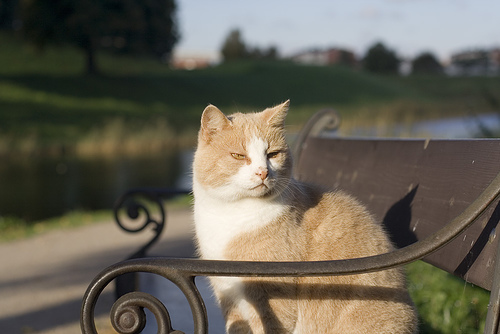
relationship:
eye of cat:
[266, 149, 283, 160] [164, 121, 441, 315]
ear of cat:
[201, 103, 233, 136] [186, 98, 420, 334]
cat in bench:
[186, 98, 420, 334] [121, 107, 499, 327]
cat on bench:
[186, 98, 420, 334] [57, 74, 499, 332]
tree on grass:
[0, 0, 180, 72] [133, 75, 329, 100]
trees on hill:
[221, 25, 279, 59] [185, 57, 414, 110]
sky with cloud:
[174, 1, 496, 56] [357, 6, 381, 23]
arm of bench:
[79, 252, 199, 332] [78, 110, 500, 334]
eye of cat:
[226, 150, 249, 163] [186, 98, 420, 334]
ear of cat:
[196, 101, 233, 137] [186, 98, 420, 334]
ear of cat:
[267, 99, 292, 126] [186, 98, 420, 334]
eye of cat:
[268, 147, 285, 157] [186, 98, 420, 334]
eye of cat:
[225, 146, 248, 163] [186, 98, 420, 334]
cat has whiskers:
[186, 98, 420, 334] [273, 174, 311, 202]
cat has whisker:
[186, 98, 420, 334] [271, 178, 298, 200]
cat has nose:
[186, 98, 420, 334] [252, 164, 272, 178]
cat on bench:
[114, 70, 429, 332] [72, 130, 497, 331]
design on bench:
[70, 251, 212, 331] [78, 105, 499, 332]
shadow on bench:
[372, 187, 424, 242] [308, 115, 489, 310]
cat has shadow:
[186, 98, 420, 334] [372, 187, 424, 242]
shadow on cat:
[218, 280, 413, 332] [186, 98, 420, 334]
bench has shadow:
[78, 105, 499, 332] [218, 280, 413, 332]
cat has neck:
[186, 98, 420, 334] [179, 195, 289, 220]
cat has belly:
[186, 98, 420, 334] [204, 232, 274, 326]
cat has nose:
[186, 98, 420, 334] [249, 148, 277, 182]